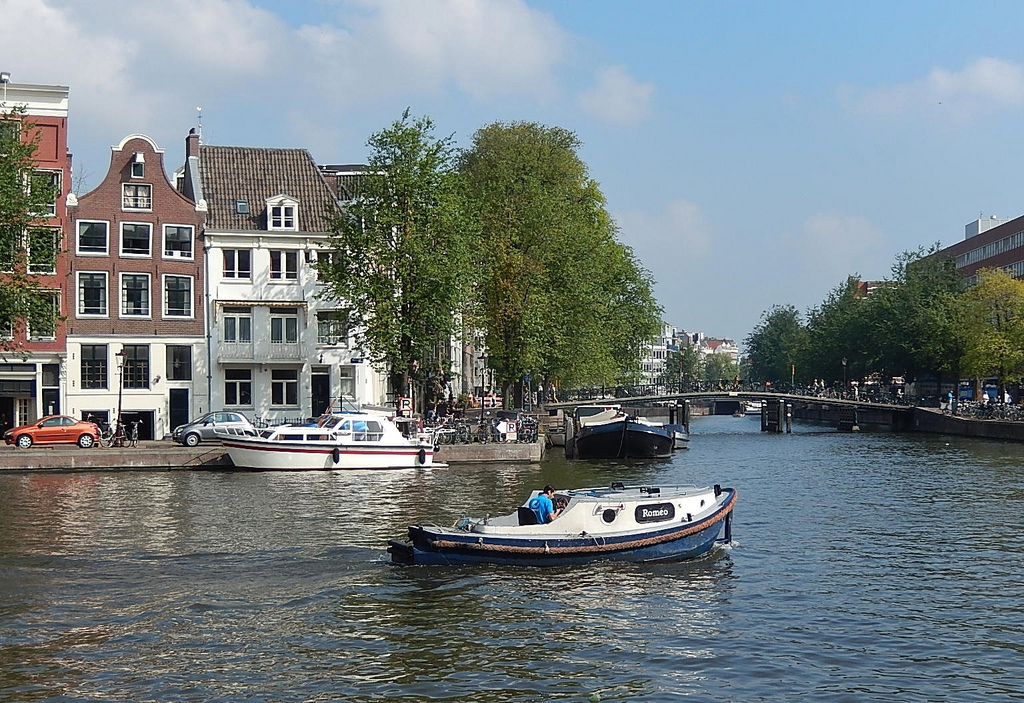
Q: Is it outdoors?
A: Yes, it is outdoors.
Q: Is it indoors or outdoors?
A: It is outdoors.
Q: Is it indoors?
A: No, it is outdoors.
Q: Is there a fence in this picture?
A: No, there are no fences.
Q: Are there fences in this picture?
A: No, there are no fences.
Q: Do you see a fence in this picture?
A: No, there are no fences.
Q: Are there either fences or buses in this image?
A: No, there are no fences or buses.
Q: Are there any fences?
A: No, there are no fences.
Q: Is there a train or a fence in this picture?
A: No, there are no fences or trains.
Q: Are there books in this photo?
A: No, there are no books.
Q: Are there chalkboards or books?
A: No, there are no books or chalkboards.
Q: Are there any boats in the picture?
A: Yes, there is a boat.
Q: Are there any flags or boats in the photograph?
A: Yes, there is a boat.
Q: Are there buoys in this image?
A: No, there are no buoys.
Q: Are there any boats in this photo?
A: Yes, there is a boat.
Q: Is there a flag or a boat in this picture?
A: Yes, there is a boat.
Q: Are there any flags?
A: No, there are no flags.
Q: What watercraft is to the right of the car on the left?
A: The watercraft is a boat.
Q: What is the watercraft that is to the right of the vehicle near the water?
A: The watercraft is a boat.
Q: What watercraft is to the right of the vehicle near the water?
A: The watercraft is a boat.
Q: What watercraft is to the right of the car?
A: The watercraft is a boat.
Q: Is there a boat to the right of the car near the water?
A: Yes, there is a boat to the right of the car.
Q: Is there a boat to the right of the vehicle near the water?
A: Yes, there is a boat to the right of the car.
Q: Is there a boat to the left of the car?
A: No, the boat is to the right of the car.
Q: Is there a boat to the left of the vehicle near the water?
A: No, the boat is to the right of the car.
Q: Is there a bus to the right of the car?
A: No, there is a boat to the right of the car.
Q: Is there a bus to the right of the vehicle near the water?
A: No, there is a boat to the right of the car.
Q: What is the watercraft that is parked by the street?
A: The watercraft is a boat.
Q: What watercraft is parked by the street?
A: The watercraft is a boat.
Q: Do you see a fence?
A: No, there are no fences.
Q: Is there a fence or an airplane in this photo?
A: No, there are no fences or airplanes.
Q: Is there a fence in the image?
A: No, there are no fences.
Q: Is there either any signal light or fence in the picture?
A: No, there are no fences or traffic lights.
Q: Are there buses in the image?
A: No, there are no buses.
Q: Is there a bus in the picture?
A: No, there are no buses.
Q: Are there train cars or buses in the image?
A: No, there are no buses or train cars.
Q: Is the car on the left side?
A: Yes, the car is on the left of the image.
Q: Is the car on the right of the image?
A: No, the car is on the left of the image.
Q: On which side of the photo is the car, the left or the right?
A: The car is on the left of the image.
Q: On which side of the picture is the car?
A: The car is on the left of the image.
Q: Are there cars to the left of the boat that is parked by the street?
A: Yes, there is a car to the left of the boat.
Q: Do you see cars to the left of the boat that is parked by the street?
A: Yes, there is a car to the left of the boat.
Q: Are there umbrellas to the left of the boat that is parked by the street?
A: No, there is a car to the left of the boat.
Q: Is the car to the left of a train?
A: No, the car is to the left of the boat.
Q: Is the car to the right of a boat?
A: No, the car is to the left of a boat.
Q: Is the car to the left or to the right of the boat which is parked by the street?
A: The car is to the left of the boat.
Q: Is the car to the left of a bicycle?
A: Yes, the car is to the left of a bicycle.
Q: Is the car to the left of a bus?
A: No, the car is to the left of a bicycle.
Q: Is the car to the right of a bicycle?
A: No, the car is to the left of a bicycle.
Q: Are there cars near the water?
A: Yes, there is a car near the water.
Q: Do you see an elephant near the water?
A: No, there is a car near the water.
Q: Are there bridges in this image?
A: Yes, there is a bridge.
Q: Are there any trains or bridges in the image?
A: Yes, there is a bridge.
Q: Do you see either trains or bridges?
A: Yes, there is a bridge.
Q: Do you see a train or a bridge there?
A: Yes, there is a bridge.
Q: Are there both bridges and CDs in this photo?
A: No, there is a bridge but no cds.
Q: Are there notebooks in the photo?
A: No, there are no notebooks.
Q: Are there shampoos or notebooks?
A: No, there are no notebooks or shampoos.